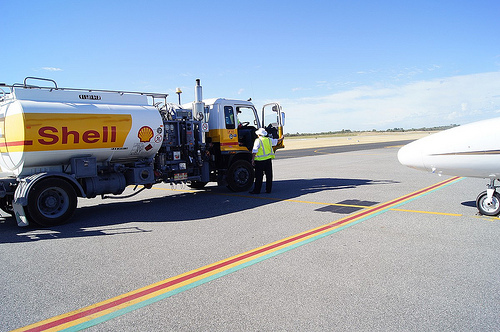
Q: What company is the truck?
A: Shell.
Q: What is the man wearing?
A: Yellow reflective jacket.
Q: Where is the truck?
A: At the airport.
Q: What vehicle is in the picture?
A: A gas truck.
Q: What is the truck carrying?
A: Gasoline.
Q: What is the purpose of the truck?
A: To fill planes with gas.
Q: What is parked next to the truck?
A: Plane.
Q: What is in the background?
A: Trees.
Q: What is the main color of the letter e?
A: Red.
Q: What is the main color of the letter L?
A: Red.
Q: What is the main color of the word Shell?
A: Red.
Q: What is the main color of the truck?
A: Yellow.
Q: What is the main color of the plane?
A: White.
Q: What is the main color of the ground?
A: Gray.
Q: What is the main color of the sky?
A: Blue.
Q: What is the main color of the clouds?
A: White.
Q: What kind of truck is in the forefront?
A: A Shell fueling truck.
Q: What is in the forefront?
A: A concrete runway.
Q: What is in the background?
A: A blue sky.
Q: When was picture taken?
A: Daytime.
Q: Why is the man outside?
A: Working.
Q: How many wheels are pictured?
A: 3.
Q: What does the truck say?
A: Shell.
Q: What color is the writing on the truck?
A: Red.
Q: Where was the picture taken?
A: Airport.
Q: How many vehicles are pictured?
A: 1.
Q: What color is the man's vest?
A: Green.